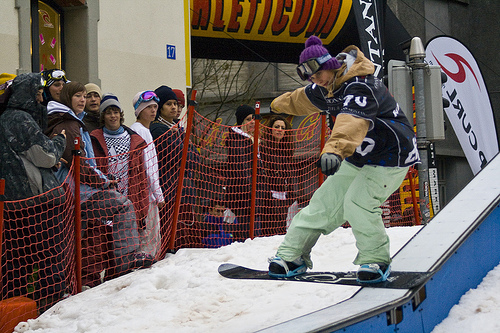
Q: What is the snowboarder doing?
A: Performing a trick.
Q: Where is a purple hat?
A: On snowboarder's head.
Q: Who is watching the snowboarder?
A: Spectators.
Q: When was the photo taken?
A: During daytime.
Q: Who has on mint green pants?
A: Man snowboarding.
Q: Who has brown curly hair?
A: Woman behind fence on right.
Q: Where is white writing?
A: On black sign.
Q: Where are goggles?
A: Over purple hat.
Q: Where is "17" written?
A: On blue sign.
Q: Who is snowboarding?
A: A woman.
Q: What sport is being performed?
A: Snowboarding.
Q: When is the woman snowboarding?
A: During daylight hours.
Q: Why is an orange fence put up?
A: To keep the spectators back.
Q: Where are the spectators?
A: Behind the orange fence.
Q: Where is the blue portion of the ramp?
A: On the bottom.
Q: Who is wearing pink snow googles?
A: A boy standing behind the fence.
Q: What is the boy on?
A: The snowboard.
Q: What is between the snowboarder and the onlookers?
A: A red fence.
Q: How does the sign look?
A: The sign is red, white and black.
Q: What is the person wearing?
A: The person is wearing a purple knit hat.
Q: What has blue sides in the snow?
A: A snowboard ramp.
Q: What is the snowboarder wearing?
A: A brown and blue jacket.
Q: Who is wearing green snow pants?
A: The snowboarder.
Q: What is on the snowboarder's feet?
A: A snowboard.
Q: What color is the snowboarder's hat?
A: Purple.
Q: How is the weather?
A: Snowy.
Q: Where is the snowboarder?
A: On the ramp.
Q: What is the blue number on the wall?
A: 17.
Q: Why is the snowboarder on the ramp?
A: To do a trick.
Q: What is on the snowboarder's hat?
A: Goggle.